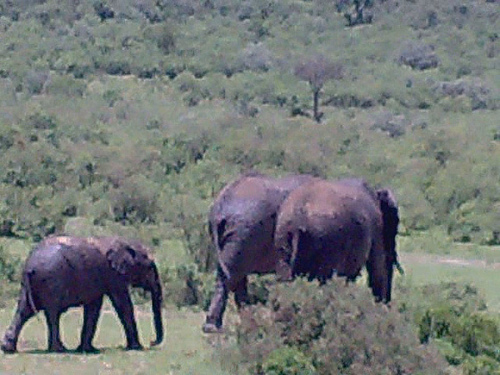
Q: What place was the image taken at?
A: It was taken at the field.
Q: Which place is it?
A: It is a field.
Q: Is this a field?
A: Yes, it is a field.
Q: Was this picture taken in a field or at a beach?
A: It was taken at a field.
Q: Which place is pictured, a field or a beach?
A: It is a field.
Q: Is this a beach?
A: No, it is a field.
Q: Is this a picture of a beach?
A: No, the picture is showing a field.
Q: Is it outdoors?
A: Yes, it is outdoors.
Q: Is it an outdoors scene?
A: Yes, it is outdoors.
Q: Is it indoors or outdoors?
A: It is outdoors.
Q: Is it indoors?
A: No, it is outdoors.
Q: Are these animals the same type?
A: Yes, all the animals are elephants.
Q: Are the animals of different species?
A: No, all the animals are elephants.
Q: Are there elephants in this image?
A: Yes, there is an elephant.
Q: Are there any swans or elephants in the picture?
A: Yes, there is an elephant.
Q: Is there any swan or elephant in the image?
A: Yes, there is an elephant.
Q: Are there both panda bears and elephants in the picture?
A: No, there is an elephant but no pandas.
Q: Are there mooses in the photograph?
A: No, there are no mooses.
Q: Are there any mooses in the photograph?
A: No, there are no mooses.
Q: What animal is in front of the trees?
A: The elephant is in front of the trees.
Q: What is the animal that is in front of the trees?
A: The animal is an elephant.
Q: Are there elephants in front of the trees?
A: Yes, there is an elephant in front of the trees.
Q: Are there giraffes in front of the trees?
A: No, there is an elephant in front of the trees.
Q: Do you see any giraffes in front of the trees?
A: No, there is an elephant in front of the trees.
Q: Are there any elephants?
A: Yes, there are elephants.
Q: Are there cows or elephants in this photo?
A: Yes, there are elephants.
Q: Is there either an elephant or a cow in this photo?
A: Yes, there are elephants.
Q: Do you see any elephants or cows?
A: Yes, there are elephants.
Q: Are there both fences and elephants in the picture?
A: No, there are elephants but no fences.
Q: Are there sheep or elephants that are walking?
A: Yes, the elephants are walking.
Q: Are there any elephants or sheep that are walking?
A: Yes, the elephants are walking.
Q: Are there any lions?
A: No, there are no lions.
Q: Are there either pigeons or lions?
A: No, there are no lions or pigeons.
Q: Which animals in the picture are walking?
A: The animals are elephants.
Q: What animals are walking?
A: The animals are elephants.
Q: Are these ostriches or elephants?
A: These are elephants.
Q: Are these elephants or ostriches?
A: These are elephants.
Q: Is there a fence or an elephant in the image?
A: Yes, there is an elephant.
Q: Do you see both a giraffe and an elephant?
A: No, there is an elephant but no giraffes.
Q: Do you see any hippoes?
A: No, there are no hippoes.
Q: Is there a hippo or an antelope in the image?
A: No, there are no hippoes or antelopes.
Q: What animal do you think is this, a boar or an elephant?
A: This is an elephant.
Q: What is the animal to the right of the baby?
A: The animal is an elephant.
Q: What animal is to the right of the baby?
A: The animal is an elephant.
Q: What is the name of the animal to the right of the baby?
A: The animal is an elephant.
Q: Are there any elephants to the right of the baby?
A: Yes, there is an elephant to the right of the baby.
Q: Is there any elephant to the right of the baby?
A: Yes, there is an elephant to the right of the baby.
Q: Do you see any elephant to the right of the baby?
A: Yes, there is an elephant to the right of the baby.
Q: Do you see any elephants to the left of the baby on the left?
A: No, the elephant is to the right of the baby.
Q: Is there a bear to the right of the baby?
A: No, there is an elephant to the right of the baby.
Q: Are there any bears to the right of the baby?
A: No, there is an elephant to the right of the baby.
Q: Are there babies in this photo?
A: Yes, there is a baby.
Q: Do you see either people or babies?
A: Yes, there is a baby.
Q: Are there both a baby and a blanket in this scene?
A: No, there is a baby but no blankets.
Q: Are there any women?
A: No, there are no women.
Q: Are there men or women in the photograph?
A: No, there are no women or men.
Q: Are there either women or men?
A: No, there are no women or men.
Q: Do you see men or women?
A: No, there are no women or men.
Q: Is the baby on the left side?
A: Yes, the baby is on the left of the image.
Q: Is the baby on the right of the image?
A: No, the baby is on the left of the image.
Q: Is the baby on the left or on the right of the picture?
A: The baby is on the left of the image.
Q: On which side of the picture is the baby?
A: The baby is on the left of the image.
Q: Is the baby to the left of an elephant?
A: Yes, the baby is to the left of an elephant.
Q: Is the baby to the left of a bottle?
A: No, the baby is to the left of an elephant.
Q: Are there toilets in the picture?
A: No, there are no toilets.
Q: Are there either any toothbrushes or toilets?
A: No, there are no toilets or toothbrushes.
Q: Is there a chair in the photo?
A: No, there are no chairs.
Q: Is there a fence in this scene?
A: No, there are no fences.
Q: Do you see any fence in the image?
A: No, there are no fences.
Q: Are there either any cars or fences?
A: No, there are no fences or cars.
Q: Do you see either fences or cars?
A: No, there are no fences or cars.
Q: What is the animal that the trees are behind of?
A: The animal is an elephant.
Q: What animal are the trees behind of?
A: The trees are behind the elephant.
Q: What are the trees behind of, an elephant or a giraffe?
A: The trees are behind an elephant.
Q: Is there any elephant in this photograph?
A: Yes, there is an elephant.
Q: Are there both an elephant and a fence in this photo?
A: No, there is an elephant but no fences.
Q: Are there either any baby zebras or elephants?
A: Yes, there is a baby elephant.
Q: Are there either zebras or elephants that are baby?
A: Yes, the elephant is a baby.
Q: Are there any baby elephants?
A: Yes, there is a baby elephant.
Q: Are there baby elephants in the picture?
A: Yes, there is a baby elephant.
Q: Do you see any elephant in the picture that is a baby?
A: Yes, there is an elephant that is a baby.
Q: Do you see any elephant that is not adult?
A: Yes, there is an baby elephant.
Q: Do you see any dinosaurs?
A: No, there are no dinosaurs.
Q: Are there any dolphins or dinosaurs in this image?
A: No, there are no dinosaurs or dolphins.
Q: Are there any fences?
A: No, there are no fences.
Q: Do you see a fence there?
A: No, there are no fences.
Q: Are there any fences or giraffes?
A: No, there are no fences or giraffes.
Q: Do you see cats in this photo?
A: No, there are no cats.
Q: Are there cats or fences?
A: No, there are no cats or fences.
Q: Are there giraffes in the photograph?
A: No, there are no giraffes.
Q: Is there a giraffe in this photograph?
A: No, there are no giraffes.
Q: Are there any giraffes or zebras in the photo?
A: No, there are no giraffes or zebras.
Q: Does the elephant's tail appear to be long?
A: Yes, the tail is long.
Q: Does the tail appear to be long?
A: Yes, the tail is long.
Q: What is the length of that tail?
A: The tail is long.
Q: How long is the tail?
A: The tail is long.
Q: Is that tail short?
A: No, the tail is long.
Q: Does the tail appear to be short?
A: No, the tail is long.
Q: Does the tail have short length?
A: No, the tail is long.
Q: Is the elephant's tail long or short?
A: The tail is long.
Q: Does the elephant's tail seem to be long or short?
A: The tail is long.